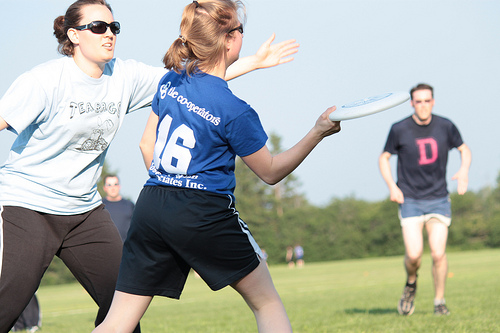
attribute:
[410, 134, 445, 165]
letter — red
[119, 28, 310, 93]
arm — extended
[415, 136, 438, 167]
d — pink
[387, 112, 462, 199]
shirt — dark blue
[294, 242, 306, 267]
people — blurry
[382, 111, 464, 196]
shirt — gray, pink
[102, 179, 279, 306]
shorts — black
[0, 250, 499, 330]
green grass — well groomed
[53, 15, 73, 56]
ponytail — brown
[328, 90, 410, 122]
frisbee — White 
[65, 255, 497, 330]
grass — green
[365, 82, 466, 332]
man — running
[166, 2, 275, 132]
person — playing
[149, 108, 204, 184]
sport number — 16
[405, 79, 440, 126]
face — white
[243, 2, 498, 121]
sky — clear, blue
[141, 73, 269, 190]
shirt — blue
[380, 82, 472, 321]
young person — playing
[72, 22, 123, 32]
sun glasses — black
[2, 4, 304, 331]
person — playing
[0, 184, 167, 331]
pant — black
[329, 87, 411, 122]
frisbee — white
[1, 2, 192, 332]
woman — attempting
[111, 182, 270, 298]
shorts — black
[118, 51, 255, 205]
shirt — blue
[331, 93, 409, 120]
frisbee — round, white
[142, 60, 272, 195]
shirt — blue, white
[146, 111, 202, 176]
number — 16